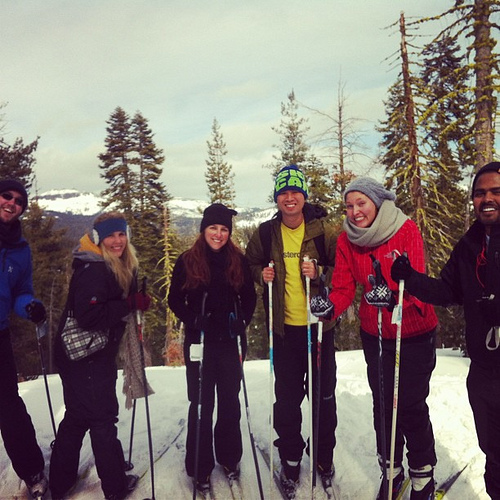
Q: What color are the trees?
A: Green.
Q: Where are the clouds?
A: The sky.